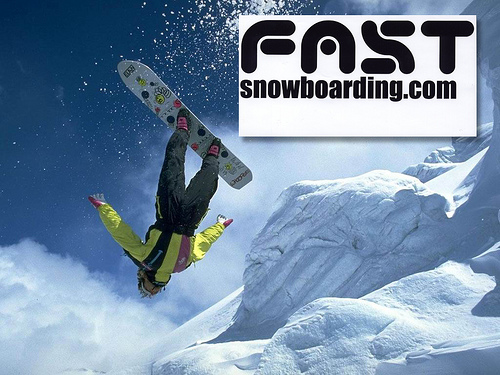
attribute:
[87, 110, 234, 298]
snowboarder — flipping, inverted, upside down, snowboarding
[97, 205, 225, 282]
coat — yellow, black, pink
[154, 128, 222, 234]
pants — black, yellow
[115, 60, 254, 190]
snowboard — white, midair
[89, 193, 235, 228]
gloves — pink, white, red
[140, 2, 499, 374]
snow — white, thick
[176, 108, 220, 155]
boots — pink, black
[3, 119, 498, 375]
clouds — white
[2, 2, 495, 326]
sky — blue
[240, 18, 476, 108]
logo — white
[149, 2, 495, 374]
ice — cracked